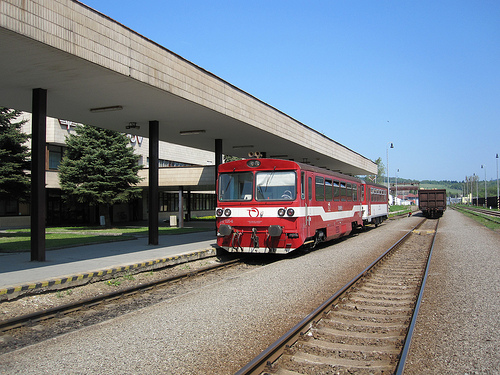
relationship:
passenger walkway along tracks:
[12, 201, 305, 326] [12, 208, 495, 366]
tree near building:
[53, 119, 153, 233] [4, 112, 242, 246]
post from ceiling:
[141, 112, 171, 254] [0, 1, 408, 181]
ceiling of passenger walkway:
[0, 1, 408, 181] [0, 229, 216, 288]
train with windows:
[214, 158, 394, 265] [307, 173, 367, 204]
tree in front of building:
[55, 124, 145, 226] [6, 113, 230, 241]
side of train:
[294, 169, 387, 252] [214, 158, 394, 265]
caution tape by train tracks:
[4, 247, 217, 297] [4, 255, 245, 351]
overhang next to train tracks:
[4, 1, 380, 176] [14, 260, 249, 355]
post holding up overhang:
[31, 85, 46, 265] [4, 1, 380, 176]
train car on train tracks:
[410, 180, 452, 231] [293, 184, 459, 361]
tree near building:
[55, 124, 145, 226] [26, 117, 266, 258]